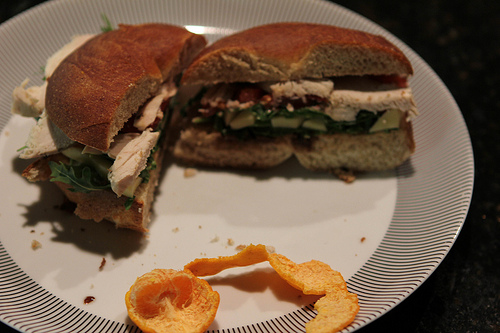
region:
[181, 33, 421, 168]
this is a burger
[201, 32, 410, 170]
the burger is halfy cut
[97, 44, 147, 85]
the ban is brown in color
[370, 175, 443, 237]
this is a plate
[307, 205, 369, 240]
the plate is white in color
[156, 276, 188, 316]
this is an orange pill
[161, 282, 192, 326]
the pill is orange in color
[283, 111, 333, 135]
these are veges in the burger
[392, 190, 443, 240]
the plate is big in size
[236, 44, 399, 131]
the burger is big in size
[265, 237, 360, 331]
a chip on the plate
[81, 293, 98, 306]
a spot of sauce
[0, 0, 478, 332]
a black and white plate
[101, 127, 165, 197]
a piece of white chicken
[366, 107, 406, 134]
a green pickle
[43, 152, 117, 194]
a leaf of green lettuce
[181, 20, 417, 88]
a slice of brown bread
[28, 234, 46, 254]
a crumb on the plate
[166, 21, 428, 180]
half of a sandwich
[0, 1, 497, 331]
a black counter top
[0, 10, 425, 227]
sandwich on plate cut in half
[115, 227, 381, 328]
half peeled orange on plate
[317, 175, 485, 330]
black and white striped plate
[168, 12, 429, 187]
pickles on turkey sandwhich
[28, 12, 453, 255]
turkey sandwich on plate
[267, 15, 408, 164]
turkey sandwich on wheat bread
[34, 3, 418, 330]
sandwich and orange on plate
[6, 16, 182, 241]
turkey on Kaiser roll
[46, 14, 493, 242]
kaiser roll with turkey, lettuce, bacon and cucumber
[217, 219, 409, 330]
orange peel on a plate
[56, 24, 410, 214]
a wheat bread sandwich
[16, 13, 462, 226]
a sandwich on a white plate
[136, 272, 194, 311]
half of a clementine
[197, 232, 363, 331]
clementine peel on a white plate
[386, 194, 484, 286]
plate with a white and black stripes edge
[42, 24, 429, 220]
a sandwich cut in two halves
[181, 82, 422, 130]
a mix of chicken, tomatoes, salad and cucumber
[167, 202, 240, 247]
bread crumbs on a plate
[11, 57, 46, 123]
a discarded bit of chicken on a plate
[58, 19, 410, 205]
a chicken sandwich with salad and tomatoes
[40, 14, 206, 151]
a brown slice of bread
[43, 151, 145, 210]
a green leaf of lettuce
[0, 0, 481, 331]
a white and black plate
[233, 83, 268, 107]
a slice of red tomato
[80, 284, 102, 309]
a spot of sauce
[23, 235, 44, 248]
a crumb on the plate